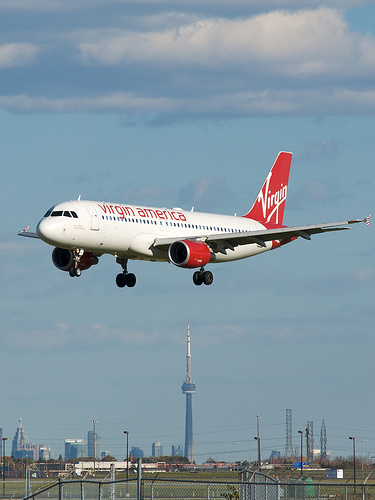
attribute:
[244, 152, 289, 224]
tail — here, red, white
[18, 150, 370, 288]
airplane — red ad white, here, white, streamlined, landing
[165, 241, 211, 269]
engine — here, leftmost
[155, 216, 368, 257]
wing — here, leftmost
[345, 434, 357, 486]
light pole — black, here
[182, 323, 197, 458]
tower — in distance, tall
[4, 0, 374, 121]
clouds — white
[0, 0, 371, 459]
sky — blue, partly cloudy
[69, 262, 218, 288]
wheels — black, here, round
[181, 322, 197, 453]
spire — in distance, here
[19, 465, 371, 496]
metal fence — here, chain link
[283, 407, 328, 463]
metal structures — tall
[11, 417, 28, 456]
building — tiered, white, short, tall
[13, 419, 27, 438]
roof — slanted